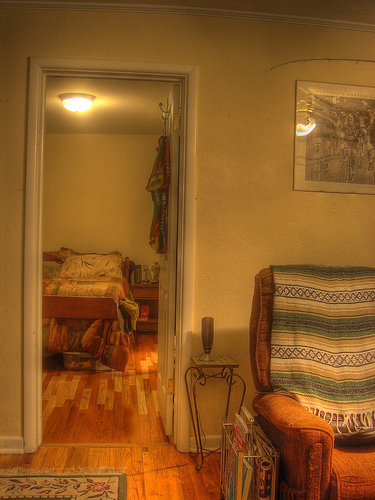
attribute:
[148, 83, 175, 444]
door — open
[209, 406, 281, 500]
magazine rack — wire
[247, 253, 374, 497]
chair — brown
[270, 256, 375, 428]
blanket — striped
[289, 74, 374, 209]
picture — black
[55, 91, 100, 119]
light — on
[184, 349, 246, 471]
table — small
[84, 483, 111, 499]
pattern — floral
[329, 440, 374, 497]
cushion — brown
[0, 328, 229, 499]
floor — wood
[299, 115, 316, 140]
light — reflecting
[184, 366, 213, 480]
legs — curved